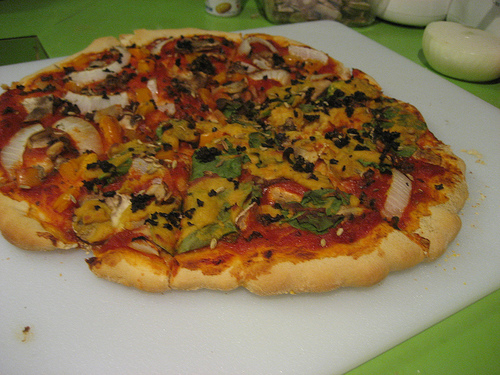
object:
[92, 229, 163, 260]
sauce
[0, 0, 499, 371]
surface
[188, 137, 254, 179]
green spinach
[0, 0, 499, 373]
counter top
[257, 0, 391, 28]
glass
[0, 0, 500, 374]
table cloth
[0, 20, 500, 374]
cutting board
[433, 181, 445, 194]
pepper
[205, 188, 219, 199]
pepper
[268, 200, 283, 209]
pepper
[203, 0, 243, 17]
salt shaker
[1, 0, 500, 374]
table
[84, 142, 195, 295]
pizza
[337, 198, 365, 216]
mustard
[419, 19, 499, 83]
onion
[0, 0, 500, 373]
counter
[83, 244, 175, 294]
crust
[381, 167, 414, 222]
onion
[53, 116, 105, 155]
onion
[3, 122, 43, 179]
onion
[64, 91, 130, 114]
onion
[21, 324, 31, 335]
crumb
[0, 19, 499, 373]
plate